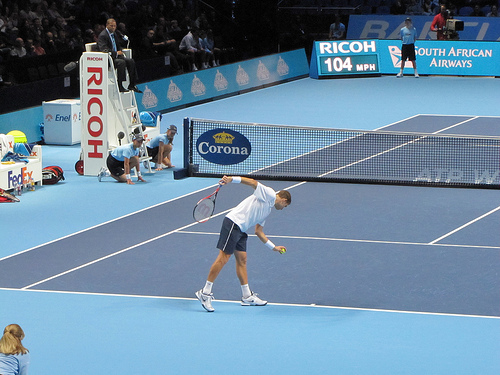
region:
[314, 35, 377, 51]
advertisement for Ricoh on the sign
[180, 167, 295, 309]
tennis player getting ready to serve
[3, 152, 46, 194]
FedEx logo on the table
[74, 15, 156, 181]
Ricoh logo on the side of the referee chair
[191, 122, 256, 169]
Corona logo on the tennis net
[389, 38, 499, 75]
South African Airways advertisement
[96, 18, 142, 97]
referee wearing a suit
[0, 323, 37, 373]
woman with blond hair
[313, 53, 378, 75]
display shows 104 MPH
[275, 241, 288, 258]
yellow tennis ball in the man's hand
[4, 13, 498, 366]
a tennis match on an indoor court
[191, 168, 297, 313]
male tennis player preparing to serve the ball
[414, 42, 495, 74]
advertisement for South African Airways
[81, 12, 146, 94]
Tenns game official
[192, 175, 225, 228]
red, black and white tennis racket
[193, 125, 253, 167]
Corona beer court advertisement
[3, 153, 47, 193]
white, purple and orange FedEx Advertisement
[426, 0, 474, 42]
man recording the tennis event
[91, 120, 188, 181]
2 workers monitoring the match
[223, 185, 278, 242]
white athletic t-shirt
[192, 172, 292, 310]
a tennis player on a tennis court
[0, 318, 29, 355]
a blonde woman sitting on the side of a tennis court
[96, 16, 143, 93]
a presenter wearing a black suit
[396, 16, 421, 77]
person standing in the back of a tennis court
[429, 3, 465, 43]
a cameraman behind a TV camera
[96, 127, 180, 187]
two people ready to sprint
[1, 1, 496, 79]
spectators in the bleachers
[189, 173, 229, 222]
man holding a tennis racket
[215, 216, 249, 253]
man wearing blue shorts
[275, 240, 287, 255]
man holding a yellow ball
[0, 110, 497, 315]
man close to the edge of a blue tennis court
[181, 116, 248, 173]
brand logo on the end of a tennis net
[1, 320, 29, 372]
woman with dark blonde hair is seen from behind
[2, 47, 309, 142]
low blue barrier at edge of court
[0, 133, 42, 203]
items strewn on a seating area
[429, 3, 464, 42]
person operating a large television camera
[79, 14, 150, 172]
man in a suit sitting in an elevated seat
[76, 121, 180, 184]
two people kneeling at base on elevated seat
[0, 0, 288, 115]
audience is in shadow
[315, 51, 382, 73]
an indicator of speed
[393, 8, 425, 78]
man in a blue shirt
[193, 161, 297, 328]
man in a white shirt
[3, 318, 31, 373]
women with blonde hair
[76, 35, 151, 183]
high chair with red letters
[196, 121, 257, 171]
blue sign with white letters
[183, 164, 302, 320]
man swinging a tennis racket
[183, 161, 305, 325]
man wears white tennis shoes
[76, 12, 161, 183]
man sits in high chair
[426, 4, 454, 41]
camera man in a red shirt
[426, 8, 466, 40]
man holds camera